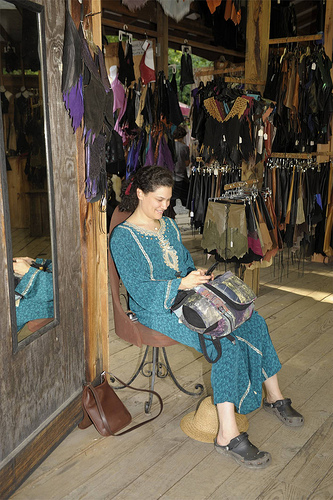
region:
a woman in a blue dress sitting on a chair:
[108, 165, 303, 472]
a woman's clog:
[213, 436, 270, 469]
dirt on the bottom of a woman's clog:
[223, 458, 267, 470]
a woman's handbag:
[78, 374, 135, 436]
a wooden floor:
[57, 440, 212, 496]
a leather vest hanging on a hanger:
[80, 14, 116, 137]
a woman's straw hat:
[182, 397, 211, 444]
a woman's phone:
[203, 261, 222, 277]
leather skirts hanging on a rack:
[204, 178, 280, 267]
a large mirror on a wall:
[0, 0, 49, 334]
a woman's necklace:
[132, 210, 159, 231]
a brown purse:
[69, 372, 162, 438]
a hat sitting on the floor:
[181, 394, 251, 445]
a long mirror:
[1, 1, 64, 353]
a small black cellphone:
[205, 257, 219, 274]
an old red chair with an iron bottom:
[107, 204, 204, 411]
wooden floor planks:
[15, 393, 332, 499]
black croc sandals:
[264, 397, 304, 428]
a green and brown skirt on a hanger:
[198, 184, 250, 258]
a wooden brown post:
[156, 2, 170, 76]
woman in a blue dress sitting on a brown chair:
[113, 166, 307, 470]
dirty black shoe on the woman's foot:
[212, 425, 273, 469]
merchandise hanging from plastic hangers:
[205, 177, 289, 264]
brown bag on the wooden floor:
[77, 371, 164, 442]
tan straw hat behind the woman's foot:
[181, 394, 256, 445]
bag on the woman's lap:
[178, 270, 267, 361]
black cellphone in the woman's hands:
[198, 261, 221, 279]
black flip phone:
[204, 257, 222, 274]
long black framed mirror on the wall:
[4, 0, 62, 356]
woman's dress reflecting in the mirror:
[9, 253, 60, 330]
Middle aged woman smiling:
[104, 165, 212, 315]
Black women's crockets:
[217, 400, 330, 470]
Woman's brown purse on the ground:
[78, 347, 156, 449]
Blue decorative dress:
[109, 212, 187, 322]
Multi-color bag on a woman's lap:
[161, 269, 276, 362]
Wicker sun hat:
[175, 386, 252, 444]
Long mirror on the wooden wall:
[7, 58, 70, 363]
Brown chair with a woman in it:
[115, 194, 189, 404]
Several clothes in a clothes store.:
[176, 71, 319, 259]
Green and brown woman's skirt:
[201, 195, 253, 257]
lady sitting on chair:
[117, 161, 321, 468]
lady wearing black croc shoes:
[209, 421, 293, 496]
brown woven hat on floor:
[175, 397, 256, 457]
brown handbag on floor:
[72, 362, 180, 450]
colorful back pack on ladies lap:
[157, 267, 278, 344]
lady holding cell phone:
[186, 254, 233, 294]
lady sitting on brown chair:
[97, 180, 211, 430]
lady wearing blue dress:
[114, 195, 296, 419]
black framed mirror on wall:
[0, 0, 74, 358]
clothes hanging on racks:
[203, 29, 332, 287]